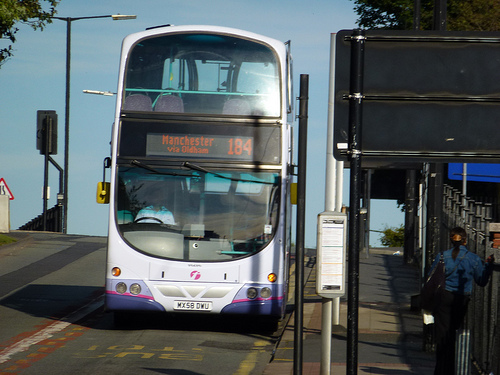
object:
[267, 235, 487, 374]
sidewalk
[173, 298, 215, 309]
license plate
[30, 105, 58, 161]
traffic light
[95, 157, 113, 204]
mirror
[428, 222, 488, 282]
person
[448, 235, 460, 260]
ponytail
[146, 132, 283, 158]
destination indicator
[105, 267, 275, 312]
headlights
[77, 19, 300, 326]
bus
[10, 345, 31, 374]
red stripe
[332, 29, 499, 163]
sign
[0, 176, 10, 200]
sign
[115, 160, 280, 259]
windshield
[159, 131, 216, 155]
letters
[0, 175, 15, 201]
border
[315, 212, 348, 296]
schedule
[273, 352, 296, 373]
sidewalk